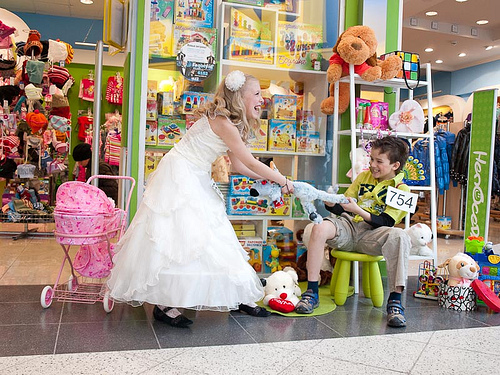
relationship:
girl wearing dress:
[103, 68, 296, 327] [109, 114, 267, 309]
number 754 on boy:
[384, 185, 419, 212] [294, 136, 418, 328]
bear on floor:
[261, 262, 302, 314] [1, 233, 499, 374]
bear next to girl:
[261, 262, 302, 314] [103, 68, 296, 327]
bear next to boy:
[261, 262, 302, 314] [294, 136, 418, 328]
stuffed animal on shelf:
[318, 25, 399, 115] [330, 57, 442, 267]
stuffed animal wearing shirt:
[318, 25, 399, 115] [328, 51, 371, 75]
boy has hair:
[294, 136, 418, 328] [369, 134, 409, 175]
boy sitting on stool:
[294, 136, 418, 328] [328, 247, 388, 309]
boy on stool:
[294, 136, 418, 328] [328, 247, 388, 309]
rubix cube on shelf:
[379, 49, 421, 81] [330, 57, 442, 267]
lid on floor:
[470, 277, 499, 312] [1, 233, 499, 374]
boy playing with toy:
[294, 136, 418, 328] [251, 161, 350, 226]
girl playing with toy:
[103, 68, 296, 327] [251, 161, 350, 226]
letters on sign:
[470, 146, 487, 239] [463, 87, 496, 245]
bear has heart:
[261, 262, 302, 314] [268, 296, 295, 314]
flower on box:
[399, 109, 413, 125] [386, 98, 425, 135]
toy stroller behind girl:
[40, 172, 136, 312] [103, 68, 296, 327]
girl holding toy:
[103, 68, 296, 327] [251, 161, 350, 226]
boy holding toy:
[294, 136, 418, 328] [251, 161, 350, 226]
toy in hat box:
[435, 252, 482, 285] [437, 281, 479, 313]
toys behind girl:
[149, 1, 328, 274] [103, 68, 296, 327]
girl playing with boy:
[103, 68, 296, 327] [294, 136, 418, 328]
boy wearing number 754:
[294, 136, 418, 328] [384, 185, 419, 212]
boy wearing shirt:
[294, 136, 418, 328] [340, 168, 413, 224]